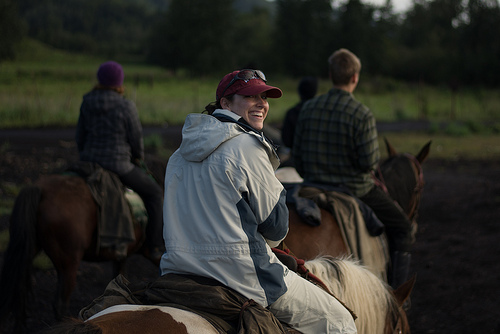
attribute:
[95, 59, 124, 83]
hat — purple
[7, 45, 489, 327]
game — long sleeve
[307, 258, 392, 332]
mane — white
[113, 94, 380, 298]
coat — tan, grey, hooded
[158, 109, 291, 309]
jacket — white, dark grey, lightweight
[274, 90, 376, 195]
flannel — green, plaid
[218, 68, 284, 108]
cap — burgundy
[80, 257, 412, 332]
horse — brown, white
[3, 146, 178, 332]
horse — brown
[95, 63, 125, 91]
hat — purple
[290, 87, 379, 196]
shirt — green, plaid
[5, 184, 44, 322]
tail — brown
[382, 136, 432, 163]
ears — perked